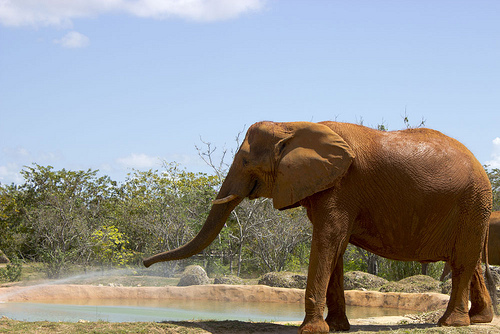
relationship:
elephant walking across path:
[84, 126, 495, 307] [17, 285, 482, 332]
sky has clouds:
[0, 0, 498, 198] [21, 1, 250, 28]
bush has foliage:
[90, 221, 142, 268] [115, 239, 118, 244]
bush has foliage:
[90, 221, 142, 268] [107, 234, 112, 239]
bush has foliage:
[90, 221, 142, 268] [105, 222, 113, 229]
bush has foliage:
[90, 221, 142, 268] [119, 258, 126, 265]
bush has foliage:
[90, 221, 142, 268] [90, 230, 97, 235]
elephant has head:
[142, 120, 493, 334] [136, 114, 359, 269]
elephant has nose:
[142, 120, 493, 334] [143, 254, 178, 279]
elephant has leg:
[142, 120, 493, 334] [292, 213, 349, 332]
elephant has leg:
[142, 120, 493, 334] [328, 267, 361, 324]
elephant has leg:
[142, 120, 493, 334] [440, 260, 471, 327]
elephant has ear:
[142, 120, 493, 334] [249, 117, 356, 209]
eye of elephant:
[248, 145, 266, 160] [142, 120, 493, 334]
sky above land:
[0, 0, 498, 198] [0, 175, 499, 331]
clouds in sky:
[5, 6, 256, 36] [326, 12, 476, 77]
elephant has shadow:
[142, 120, 493, 334] [164, 320, 304, 332]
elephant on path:
[142, 120, 493, 334] [11, 307, 487, 332]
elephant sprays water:
[142, 120, 493, 334] [5, 295, 432, 322]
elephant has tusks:
[142, 120, 493, 334] [209, 196, 238, 205]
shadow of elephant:
[163, 319, 436, 331] [142, 120, 493, 334]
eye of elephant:
[243, 159, 250, 164] [142, 120, 493, 334]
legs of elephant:
[300, 225, 498, 330] [142, 120, 493, 334]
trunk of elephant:
[142, 167, 248, 278] [142, 120, 493, 334]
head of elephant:
[141, 119, 291, 268] [142, 120, 493, 334]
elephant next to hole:
[142, 120, 493, 334] [0, 289, 409, 329]